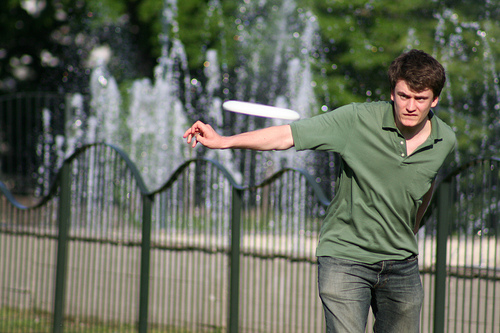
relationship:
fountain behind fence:
[25, 19, 472, 315] [2, 90, 494, 332]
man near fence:
[187, 42, 463, 331] [2, 90, 494, 332]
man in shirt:
[187, 42, 463, 331] [275, 100, 455, 264]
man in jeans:
[187, 42, 463, 331] [294, 246, 442, 332]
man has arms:
[187, 42, 463, 331] [173, 120, 472, 231]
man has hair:
[187, 42, 463, 331] [384, 45, 449, 100]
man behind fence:
[187, 42, 463, 331] [2, 90, 494, 332]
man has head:
[187, 42, 463, 331] [383, 49, 443, 128]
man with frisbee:
[187, 42, 463, 331] [208, 93, 310, 125]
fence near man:
[2, 90, 494, 332] [187, 42, 463, 331]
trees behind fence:
[0, 2, 498, 144] [2, 90, 494, 332]